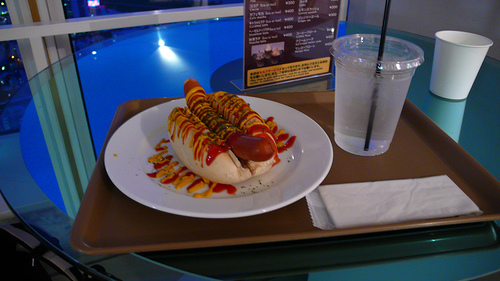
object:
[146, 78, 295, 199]
fast-food meal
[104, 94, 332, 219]
plate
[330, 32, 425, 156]
beverage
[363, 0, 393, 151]
black straw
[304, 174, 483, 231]
napkin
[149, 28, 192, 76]
reflected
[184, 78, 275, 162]
hot dog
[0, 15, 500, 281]
table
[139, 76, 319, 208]
meal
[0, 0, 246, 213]
window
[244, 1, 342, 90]
lettering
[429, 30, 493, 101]
cup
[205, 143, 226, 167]
ketchup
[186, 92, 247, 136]
mustard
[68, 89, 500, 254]
serving try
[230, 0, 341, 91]
holder